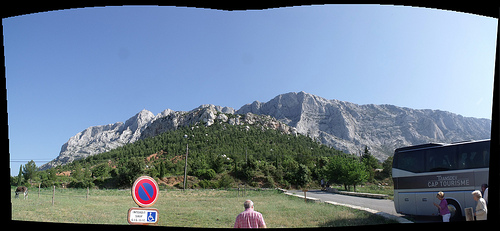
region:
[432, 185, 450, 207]
Person has light colored hair.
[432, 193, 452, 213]
Person wearing purple shirt.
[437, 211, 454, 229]
Person wearing white pants.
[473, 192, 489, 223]
Person wearing tan shirt.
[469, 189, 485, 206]
Person has gray hair.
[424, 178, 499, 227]
People standing near bus.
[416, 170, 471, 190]
Writing a long the side of bus.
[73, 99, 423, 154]
Large mountains in distance.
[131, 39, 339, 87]
Sky is clear and blue.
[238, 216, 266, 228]
Man is wearing red shirt.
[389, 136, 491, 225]
large travel bus on road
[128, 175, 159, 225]
sign informing people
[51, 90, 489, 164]
large mountain in background of picture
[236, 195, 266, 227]
man observing the sights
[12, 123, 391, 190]
hill coverd in green lush trees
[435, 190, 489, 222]
elder women observing sights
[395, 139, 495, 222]
bus stopped on the side of the road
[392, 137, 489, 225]
Tourist bus carrying people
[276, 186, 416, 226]
road bus traveled on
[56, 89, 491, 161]
steep rocky terrain in background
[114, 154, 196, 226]
This is a street sign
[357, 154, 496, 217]
This is a picture of a bus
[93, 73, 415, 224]
These are mountains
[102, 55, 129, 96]
There are no clouds in the sky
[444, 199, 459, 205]
This is a wheel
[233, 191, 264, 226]
This is a man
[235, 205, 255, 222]
This is a pink shirt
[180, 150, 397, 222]
These are pine trees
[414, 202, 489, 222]
This is a a few people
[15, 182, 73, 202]
This is an animal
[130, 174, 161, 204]
blue and red street sign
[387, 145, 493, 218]
bus stopped on road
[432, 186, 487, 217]
two people standing by bus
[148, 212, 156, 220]
blue and white handicapped sign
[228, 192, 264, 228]
man walking on grass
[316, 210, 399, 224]
shadow of bus on grass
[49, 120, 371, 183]
tree covered hill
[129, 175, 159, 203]
red cirlce with blue center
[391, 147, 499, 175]
line of windows on the bus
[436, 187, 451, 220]
woman wearing white pants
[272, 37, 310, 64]
part of the sky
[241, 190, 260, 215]
part of a head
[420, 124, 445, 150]
edge of a bus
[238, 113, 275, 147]
part of a forest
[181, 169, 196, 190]
part of a post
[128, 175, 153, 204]
part of a board